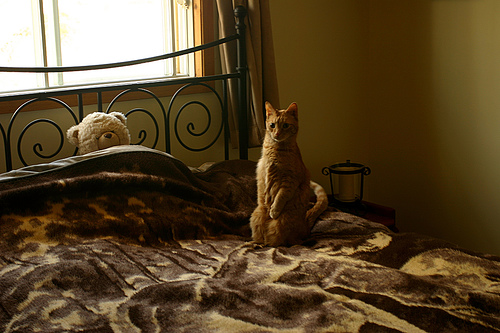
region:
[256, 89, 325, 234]
A brown cat sitted on bed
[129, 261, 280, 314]
A brown bed duvet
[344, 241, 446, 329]
A brown heavy duvet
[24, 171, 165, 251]
A brown heavy duvet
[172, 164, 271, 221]
A brown heavy duvet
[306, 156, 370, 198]
A bed side lamp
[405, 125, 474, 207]
A beige bedroom wall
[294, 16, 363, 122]
A beige bedroom wall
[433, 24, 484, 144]
A beige bedroom wall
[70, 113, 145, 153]
A beige beautiful teddy bare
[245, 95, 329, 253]
orange cat on a bed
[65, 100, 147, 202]
tucked in teddy bear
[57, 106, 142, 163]
tan teddy bear head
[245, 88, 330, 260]
cat sitting upright on a bed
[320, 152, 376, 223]
candle in a decorate basin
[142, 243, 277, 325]
brown furry blanket on a bed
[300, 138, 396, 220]
white candle in a wire container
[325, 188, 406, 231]
wooden corner of a night stand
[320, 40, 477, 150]
shadow cast on a wall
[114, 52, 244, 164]
metal ornate head board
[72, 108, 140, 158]
TEDDY BEAR IS UNDER THE COVERS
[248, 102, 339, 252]
A CAT IS SITTING ON THE BED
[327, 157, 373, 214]
DECORATIVE CANDLE IS ON THE TABLE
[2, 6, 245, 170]
HEAD BOARD HAS A SWIRL PATTERN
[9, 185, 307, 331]
BLANKET IS BROWN AND TAN IN COLOR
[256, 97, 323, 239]
CAT IS ORANGE AND TAN IN COLOR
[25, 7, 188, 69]
SUN IS SHINING IN THE WINDOW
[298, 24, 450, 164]
WALL IN BACKGROUND IS YELLOW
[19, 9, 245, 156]
HEAD BOARD IS BLACK IN COLOR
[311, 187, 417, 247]
BED SIDE TABLE IS TO THE RIGHT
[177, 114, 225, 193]
edge of a bed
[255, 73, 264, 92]
part of a curtain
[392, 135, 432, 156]
part of a wall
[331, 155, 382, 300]
edge of a bed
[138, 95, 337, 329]
a cat sitting up on a bed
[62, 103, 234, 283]
a teddy bear in a bed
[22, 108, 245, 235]
a teddy bear under the covers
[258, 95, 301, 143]
the head of a cat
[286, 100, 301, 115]
the ear of a cat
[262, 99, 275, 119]
the ear of a cat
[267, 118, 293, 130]
the eyes of a cat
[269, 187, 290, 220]
the leg of a cat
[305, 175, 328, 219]
the tail of a cat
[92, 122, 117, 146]
the face of a teddy bear